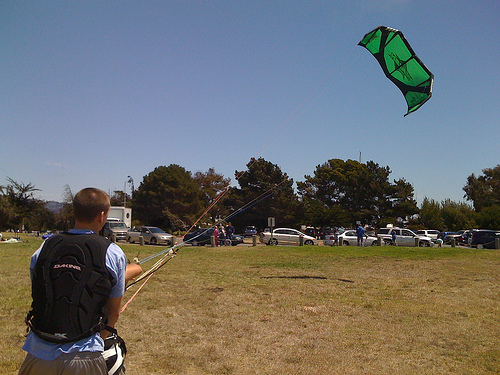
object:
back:
[266, 215, 276, 226]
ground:
[232, 240, 447, 371]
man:
[19, 186, 127, 374]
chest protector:
[25, 232, 118, 344]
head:
[74, 188, 110, 233]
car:
[260, 226, 317, 245]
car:
[324, 229, 379, 246]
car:
[374, 228, 433, 245]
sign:
[268, 217, 276, 227]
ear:
[100, 211, 105, 220]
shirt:
[23, 230, 126, 361]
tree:
[296, 159, 419, 236]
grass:
[0, 232, 499, 374]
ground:
[1, 233, 500, 374]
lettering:
[53, 264, 82, 271]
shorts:
[18, 353, 109, 375]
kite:
[358, 24, 435, 117]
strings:
[122, 44, 405, 315]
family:
[214, 223, 234, 244]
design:
[387, 53, 412, 80]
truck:
[108, 206, 133, 230]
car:
[418, 230, 441, 239]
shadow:
[262, 276, 352, 284]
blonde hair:
[74, 187, 111, 223]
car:
[125, 227, 175, 245]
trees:
[418, 196, 500, 231]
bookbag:
[100, 336, 124, 374]